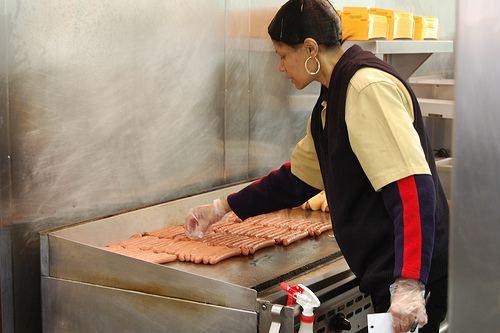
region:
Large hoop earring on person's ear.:
[290, 51, 332, 91]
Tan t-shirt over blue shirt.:
[355, 92, 427, 183]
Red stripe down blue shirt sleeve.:
[385, 169, 423, 298]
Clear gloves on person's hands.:
[383, 272, 423, 322]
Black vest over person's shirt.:
[294, 117, 380, 267]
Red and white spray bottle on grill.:
[278, 280, 318, 327]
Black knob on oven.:
[318, 302, 348, 329]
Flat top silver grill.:
[165, 217, 318, 296]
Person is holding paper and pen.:
[373, 295, 416, 330]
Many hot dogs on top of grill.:
[163, 227, 305, 265]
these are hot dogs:
[118, 189, 331, 285]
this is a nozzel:
[273, 267, 325, 331]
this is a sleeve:
[335, 80, 450, 287]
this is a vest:
[276, 46, 466, 331]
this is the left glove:
[382, 279, 430, 331]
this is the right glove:
[173, 197, 228, 237]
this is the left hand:
[386, 277, 428, 331]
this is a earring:
[301, 50, 330, 85]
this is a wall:
[66, 72, 153, 156]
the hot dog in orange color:
[199, 246, 248, 265]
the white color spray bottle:
[275, 273, 323, 328]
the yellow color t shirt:
[351, 68, 423, 186]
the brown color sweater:
[313, 38, 447, 290]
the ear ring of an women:
[301, 53, 322, 83]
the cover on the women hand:
[384, 275, 429, 332]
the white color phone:
[365, 303, 410, 329]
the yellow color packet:
[381, 1, 418, 46]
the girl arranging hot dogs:
[168, 4, 441, 296]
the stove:
[308, 262, 364, 332]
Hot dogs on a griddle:
[153, 206, 326, 278]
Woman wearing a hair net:
[262, 1, 350, 93]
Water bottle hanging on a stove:
[263, 259, 360, 331]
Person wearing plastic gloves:
[182, 183, 244, 260]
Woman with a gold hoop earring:
[270, 35, 326, 100]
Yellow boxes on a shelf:
[349, 6, 449, 60]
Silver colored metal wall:
[17, 16, 228, 188]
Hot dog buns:
[304, 188, 332, 218]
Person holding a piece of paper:
[354, 284, 426, 331]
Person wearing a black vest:
[293, 40, 458, 292]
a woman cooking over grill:
[176, 1, 450, 331]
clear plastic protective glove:
[179, 200, 226, 240]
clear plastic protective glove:
[383, 284, 426, 331]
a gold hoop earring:
[300, 56, 322, 76]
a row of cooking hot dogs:
[99, 239, 176, 270]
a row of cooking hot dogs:
[118, 225, 237, 272]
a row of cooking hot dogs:
[147, 219, 274, 259]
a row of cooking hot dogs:
[201, 214, 307, 248]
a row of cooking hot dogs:
[233, 202, 333, 238]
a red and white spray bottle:
[278, 277, 318, 331]